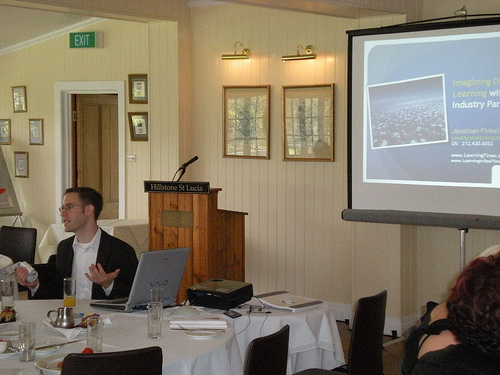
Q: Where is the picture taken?
A: A meeting.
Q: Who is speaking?
A: A man.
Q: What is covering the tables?
A: Tablecloths.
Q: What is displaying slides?
A: Slide screen.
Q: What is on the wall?
A: Yellow paneling.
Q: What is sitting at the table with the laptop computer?
A: The man.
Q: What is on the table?
A: White tablecloth.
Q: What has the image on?
A: The projector.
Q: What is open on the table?
A: Laptop.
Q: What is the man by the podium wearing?
A: Black suit jacket and white shirt.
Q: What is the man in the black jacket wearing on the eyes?
A: Eyeglasses.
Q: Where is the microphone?
A: On the podium.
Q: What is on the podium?
A: Microphone.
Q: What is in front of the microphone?
A: Nameplate.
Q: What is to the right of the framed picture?
A: White screen.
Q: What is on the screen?
A: Slideshow.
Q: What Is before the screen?
A: Long table.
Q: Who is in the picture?
A: Guy.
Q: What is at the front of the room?
A: Screen.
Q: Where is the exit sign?
A: By the door.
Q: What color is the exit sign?
A: Green.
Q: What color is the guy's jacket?
A: Black.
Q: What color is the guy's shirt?
A: White.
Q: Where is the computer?
A: Table.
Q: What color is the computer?
A: Gray.